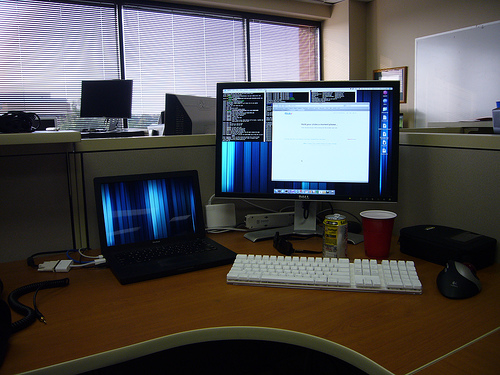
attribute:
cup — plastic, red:
[361, 208, 398, 260]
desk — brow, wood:
[2, 216, 500, 370]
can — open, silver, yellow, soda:
[324, 212, 349, 256]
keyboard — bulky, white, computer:
[220, 252, 423, 297]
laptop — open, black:
[92, 165, 236, 297]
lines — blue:
[101, 181, 194, 237]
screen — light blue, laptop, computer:
[92, 167, 206, 245]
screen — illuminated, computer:
[223, 83, 394, 191]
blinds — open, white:
[1, 0, 321, 129]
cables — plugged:
[26, 245, 106, 268]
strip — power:
[242, 211, 298, 231]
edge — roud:
[44, 324, 393, 374]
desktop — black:
[212, 78, 405, 240]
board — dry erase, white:
[412, 16, 500, 125]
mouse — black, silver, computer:
[434, 260, 481, 298]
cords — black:
[3, 274, 73, 354]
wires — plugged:
[24, 235, 107, 276]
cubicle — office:
[1, 127, 499, 369]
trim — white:
[359, 208, 398, 220]